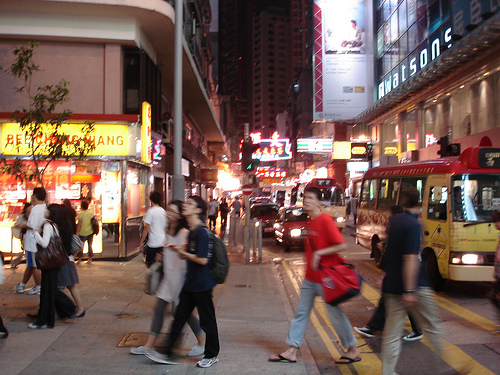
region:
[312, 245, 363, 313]
A red with blue base bag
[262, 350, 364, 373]
A pair of black slippers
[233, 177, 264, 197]
A small road sign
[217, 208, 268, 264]
A line of gray posts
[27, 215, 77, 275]
A big brown bag on the shoulder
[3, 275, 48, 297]
A pair of white rubber shoes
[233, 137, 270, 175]
The green light is on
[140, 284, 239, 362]
A black and gray pants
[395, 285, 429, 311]
A black watch on the wrist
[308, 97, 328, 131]
Edge of the big billboard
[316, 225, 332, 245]
man wearing red shirt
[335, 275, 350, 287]
red color on bag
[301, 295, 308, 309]
man wearing grey pants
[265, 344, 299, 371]
man wearing black sandals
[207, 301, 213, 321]
man wearing black pants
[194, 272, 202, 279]
man wearing blue shirt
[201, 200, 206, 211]
man has black hair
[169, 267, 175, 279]
woman wearing white shirt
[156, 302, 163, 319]
woman wearing grey tights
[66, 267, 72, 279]
woman wearing grey skirt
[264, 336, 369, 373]
a person wearing flip flops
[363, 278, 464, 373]
a person wearing tan pants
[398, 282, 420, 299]
a person wearing a wrist watch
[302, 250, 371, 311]
a person carrying a red bag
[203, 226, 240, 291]
a person wearing a black pack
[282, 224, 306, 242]
the right headlight of a car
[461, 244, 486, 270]
the right headlight of a bus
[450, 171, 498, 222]
the front windshield of a bus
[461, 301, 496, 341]
a yellow line painted in the street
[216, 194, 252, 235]
people walking on a sidewalk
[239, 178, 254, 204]
stop sign on pole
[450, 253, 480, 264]
headlight on the bus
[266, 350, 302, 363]
sandal on the man's foot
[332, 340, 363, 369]
sandal on left foot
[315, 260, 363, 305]
red bag on man's arm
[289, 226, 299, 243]
headlight on the car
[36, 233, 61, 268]
brown purse on arm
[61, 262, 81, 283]
the woman's grey skirt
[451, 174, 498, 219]
windshield on the bus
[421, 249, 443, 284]
wheel on the bus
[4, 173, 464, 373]
A crowd of people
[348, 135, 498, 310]
A yellow bus in the foreground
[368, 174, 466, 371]
A man in the foreground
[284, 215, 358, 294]
Person is wearing a red shirt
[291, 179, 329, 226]
Person has black hair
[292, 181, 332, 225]
Person's face is blurred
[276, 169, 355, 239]
A bus in the background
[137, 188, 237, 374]
Man is wearing black pants